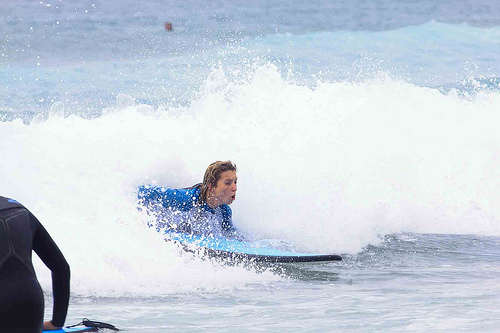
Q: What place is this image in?
A: It is at the ocean.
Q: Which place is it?
A: It is an ocean.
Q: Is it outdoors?
A: Yes, it is outdoors.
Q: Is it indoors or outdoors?
A: It is outdoors.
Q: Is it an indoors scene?
A: No, it is outdoors.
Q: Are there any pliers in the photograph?
A: No, there are no pliers.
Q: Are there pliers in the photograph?
A: No, there are no pliers.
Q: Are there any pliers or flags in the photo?
A: No, there are no pliers or flags.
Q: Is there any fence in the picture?
A: No, there are no fences.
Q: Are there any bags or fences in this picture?
A: No, there are no fences or bags.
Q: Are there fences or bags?
A: No, there are no fences or bags.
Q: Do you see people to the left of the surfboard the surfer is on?
A: Yes, there is a person to the left of the surf board.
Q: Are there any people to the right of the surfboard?
A: No, the person is to the left of the surfboard.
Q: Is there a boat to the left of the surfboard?
A: No, there is a person to the left of the surfboard.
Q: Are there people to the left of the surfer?
A: Yes, there is a person to the left of the surfer.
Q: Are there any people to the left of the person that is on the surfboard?
A: Yes, there is a person to the left of the surfer.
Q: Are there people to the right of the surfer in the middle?
A: No, the person is to the left of the surfer.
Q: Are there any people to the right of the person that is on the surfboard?
A: No, the person is to the left of the surfer.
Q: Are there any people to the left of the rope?
A: Yes, there is a person to the left of the rope.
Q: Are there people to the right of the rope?
A: No, the person is to the left of the rope.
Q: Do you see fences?
A: No, there are no fences.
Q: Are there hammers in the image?
A: No, there are no hammers.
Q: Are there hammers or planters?
A: No, there are no hammers or planters.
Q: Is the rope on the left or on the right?
A: The rope is on the left of the image.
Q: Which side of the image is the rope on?
A: The rope is on the left of the image.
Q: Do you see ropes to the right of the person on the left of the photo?
A: Yes, there is a rope to the right of the person.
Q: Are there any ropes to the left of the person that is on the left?
A: No, the rope is to the right of the person.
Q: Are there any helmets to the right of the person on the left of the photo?
A: No, there is a rope to the right of the person.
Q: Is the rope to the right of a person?
A: Yes, the rope is to the right of a person.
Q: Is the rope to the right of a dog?
A: No, the rope is to the right of a person.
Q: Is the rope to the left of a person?
A: No, the rope is to the right of a person.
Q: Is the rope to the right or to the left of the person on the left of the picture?
A: The rope is to the right of the person.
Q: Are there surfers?
A: Yes, there is a surfer.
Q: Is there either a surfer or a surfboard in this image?
A: Yes, there is a surfer.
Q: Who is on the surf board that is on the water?
A: The surfer is on the surfboard.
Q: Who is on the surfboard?
A: The surfer is on the surfboard.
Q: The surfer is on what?
A: The surfer is on the surfboard.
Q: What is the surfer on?
A: The surfer is on the surfboard.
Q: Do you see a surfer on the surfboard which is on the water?
A: Yes, there is a surfer on the surfboard.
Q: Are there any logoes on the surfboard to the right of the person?
A: No, there is a surfer on the surfboard.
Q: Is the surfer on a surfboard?
A: Yes, the surfer is on a surfboard.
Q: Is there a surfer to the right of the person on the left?
A: Yes, there is a surfer to the right of the person.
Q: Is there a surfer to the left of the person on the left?
A: No, the surfer is to the right of the person.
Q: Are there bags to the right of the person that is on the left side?
A: No, there is a surfer to the right of the person.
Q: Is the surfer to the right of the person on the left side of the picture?
A: Yes, the surfer is to the right of the person.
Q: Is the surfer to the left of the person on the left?
A: No, the surfer is to the right of the person.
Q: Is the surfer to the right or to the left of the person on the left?
A: The surfer is to the right of the person.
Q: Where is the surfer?
A: The surfer is in the water.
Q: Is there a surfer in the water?
A: Yes, there is a surfer in the water.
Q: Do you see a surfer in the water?
A: Yes, there is a surfer in the water.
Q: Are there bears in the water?
A: No, there is a surfer in the water.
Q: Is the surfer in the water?
A: Yes, the surfer is in the water.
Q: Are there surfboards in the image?
A: Yes, there is a surfboard.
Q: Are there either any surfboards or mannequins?
A: Yes, there is a surfboard.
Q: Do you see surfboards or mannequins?
A: Yes, there is a surfboard.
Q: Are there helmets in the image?
A: No, there are no helmets.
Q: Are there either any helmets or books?
A: No, there are no helmets or books.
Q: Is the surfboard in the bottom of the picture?
A: Yes, the surfboard is in the bottom of the image.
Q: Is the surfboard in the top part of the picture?
A: No, the surfboard is in the bottom of the image.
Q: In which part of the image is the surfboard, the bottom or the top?
A: The surfboard is in the bottom of the image.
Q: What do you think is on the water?
A: The surfboard is on the water.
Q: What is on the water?
A: The surfboard is on the water.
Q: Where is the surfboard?
A: The surfboard is on the water.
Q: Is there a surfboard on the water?
A: Yes, there is a surfboard on the water.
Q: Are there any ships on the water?
A: No, there is a surfboard on the water.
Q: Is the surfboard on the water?
A: Yes, the surfboard is on the water.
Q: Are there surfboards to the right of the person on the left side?
A: Yes, there is a surfboard to the right of the person.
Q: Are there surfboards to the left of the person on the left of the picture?
A: No, the surfboard is to the right of the person.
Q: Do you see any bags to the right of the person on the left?
A: No, there is a surfboard to the right of the person.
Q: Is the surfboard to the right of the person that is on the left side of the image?
A: Yes, the surfboard is to the right of the person.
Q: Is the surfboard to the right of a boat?
A: No, the surfboard is to the right of the person.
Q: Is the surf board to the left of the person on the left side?
A: No, the surf board is to the right of the person.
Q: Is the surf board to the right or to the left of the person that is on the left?
A: The surf board is to the right of the person.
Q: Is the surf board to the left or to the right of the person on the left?
A: The surf board is to the right of the person.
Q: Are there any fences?
A: No, there are no fences.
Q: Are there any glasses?
A: No, there are no glasses.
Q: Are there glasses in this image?
A: No, there are no glasses.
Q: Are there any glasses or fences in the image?
A: No, there are no glasses or fences.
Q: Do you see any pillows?
A: No, there are no pillows.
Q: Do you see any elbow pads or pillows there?
A: No, there are no pillows or elbow pads.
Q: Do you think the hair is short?
A: Yes, the hair is short.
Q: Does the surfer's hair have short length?
A: Yes, the hair is short.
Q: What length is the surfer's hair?
A: The hair is short.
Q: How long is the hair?
A: The hair is short.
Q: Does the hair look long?
A: No, the hair is short.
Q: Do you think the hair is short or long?
A: The hair is short.